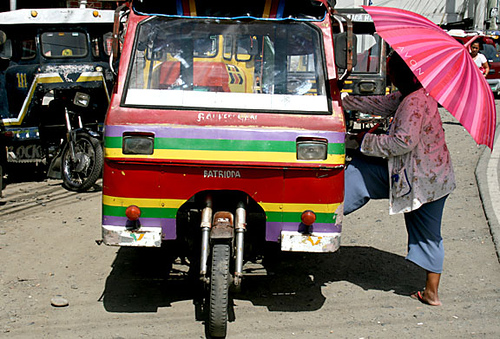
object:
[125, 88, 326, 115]
stripe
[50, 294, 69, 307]
rock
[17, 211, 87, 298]
street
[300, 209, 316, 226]
turn signal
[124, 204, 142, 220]
turn signal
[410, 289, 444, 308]
flip flop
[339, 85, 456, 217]
sweater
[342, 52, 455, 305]
woman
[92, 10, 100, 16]
light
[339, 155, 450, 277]
blue pants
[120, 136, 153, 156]
headlight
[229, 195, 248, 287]
shock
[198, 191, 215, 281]
shock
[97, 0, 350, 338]
cab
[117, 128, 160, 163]
light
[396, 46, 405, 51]
letters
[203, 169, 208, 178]
white lettering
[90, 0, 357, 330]
vehicle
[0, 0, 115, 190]
cabs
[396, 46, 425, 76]
avon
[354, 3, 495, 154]
umbrella